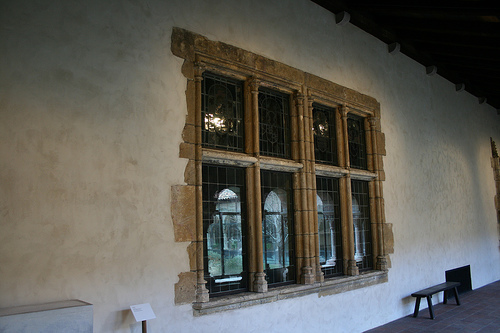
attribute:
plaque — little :
[127, 299, 159, 326]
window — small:
[312, 102, 340, 166]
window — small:
[345, 115, 371, 173]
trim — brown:
[189, 51, 389, 313]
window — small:
[198, 70, 246, 152]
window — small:
[256, 85, 295, 158]